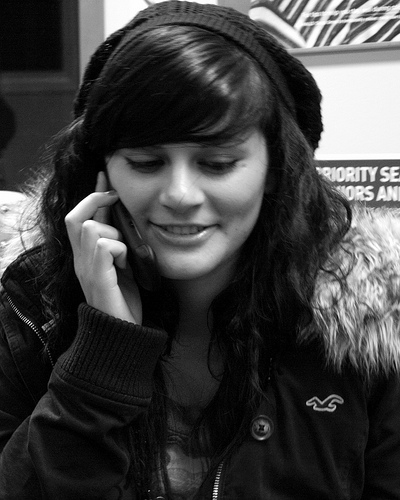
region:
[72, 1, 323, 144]
knit cap on the girl's head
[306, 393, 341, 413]
seagull embroidered on the jacket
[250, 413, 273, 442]
a button on the jacket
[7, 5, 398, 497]
girl with dark, curly hair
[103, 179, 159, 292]
cellphone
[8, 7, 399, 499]
girl talking on a cell phone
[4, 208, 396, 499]
black jacket with a fur collar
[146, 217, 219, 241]
smile on girl's face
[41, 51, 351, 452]
girl's dark curly hair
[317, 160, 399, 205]
priority seating sign behind the girl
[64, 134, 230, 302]
the girl is holding a phone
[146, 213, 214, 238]
the girl is smiling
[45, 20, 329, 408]
the girl has long hair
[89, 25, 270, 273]
the girl is looking down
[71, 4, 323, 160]
the girl is wearing a hat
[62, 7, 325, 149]
the hat is black in color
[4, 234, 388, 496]
the girl is wearing a jacket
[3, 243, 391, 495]
the jacket is black in color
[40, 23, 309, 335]
the girl is talking on a cell phone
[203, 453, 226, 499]
the jacket has a zipper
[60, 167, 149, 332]
The hand of the woman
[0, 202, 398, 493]
The woman has on a jacket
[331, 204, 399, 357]
The fur on the jacket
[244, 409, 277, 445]
A button on the jacket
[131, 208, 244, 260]
The smile of the woman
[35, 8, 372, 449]
The woman has black hair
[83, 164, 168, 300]
The woman is using her cell phone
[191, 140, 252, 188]
The eye of the woman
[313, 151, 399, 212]
The sign on the back wall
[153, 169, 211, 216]
The nose of the woman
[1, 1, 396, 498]
the photograph is black and white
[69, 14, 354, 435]
the girl on the cellphone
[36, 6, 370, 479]
the girl is talking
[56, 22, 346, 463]
the girl is looking down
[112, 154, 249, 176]
the eyes of the girl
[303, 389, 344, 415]
the logo on the jacket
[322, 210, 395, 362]
the fur on the jacket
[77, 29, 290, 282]
the girl is smiling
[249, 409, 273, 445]
the button on the jacket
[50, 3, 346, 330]
the girl wearing the hat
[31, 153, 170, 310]
Girl holding cell phone up to her ear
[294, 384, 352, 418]
Drawing of a bird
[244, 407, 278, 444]
Button on a jacket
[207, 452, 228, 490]
Zipper on a jacket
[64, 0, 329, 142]
Hat on a girl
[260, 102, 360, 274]
Long hair on a girl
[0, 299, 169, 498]
Sleeve on a jacket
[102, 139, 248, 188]
Eyes on a face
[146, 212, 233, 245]
Mouth on a face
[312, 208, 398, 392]
Faux fur on a jacket